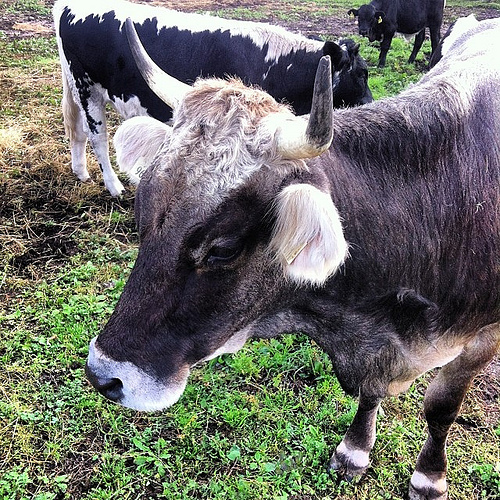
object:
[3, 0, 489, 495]
ground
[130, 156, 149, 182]
tag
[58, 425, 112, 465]
ground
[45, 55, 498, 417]
cow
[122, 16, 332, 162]
horns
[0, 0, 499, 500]
weeds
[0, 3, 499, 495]
field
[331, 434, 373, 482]
hoofs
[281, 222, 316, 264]
tag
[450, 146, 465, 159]
ground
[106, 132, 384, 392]
cow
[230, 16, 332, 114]
cow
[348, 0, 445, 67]
cow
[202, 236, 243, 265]
eye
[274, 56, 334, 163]
horn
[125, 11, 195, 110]
horn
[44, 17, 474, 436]
bovine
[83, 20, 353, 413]
head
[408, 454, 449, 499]
foot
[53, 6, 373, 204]
cow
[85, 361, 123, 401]
nose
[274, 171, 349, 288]
ear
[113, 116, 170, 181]
ear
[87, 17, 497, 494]
cow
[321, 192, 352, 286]
edge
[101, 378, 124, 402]
part